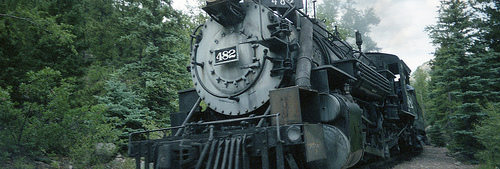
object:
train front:
[127, 0, 350, 168]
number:
[227, 49, 235, 58]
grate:
[193, 133, 250, 168]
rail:
[128, 114, 280, 135]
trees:
[472, 101, 499, 168]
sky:
[110, 0, 498, 82]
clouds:
[113, 0, 498, 82]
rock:
[93, 142, 118, 155]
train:
[126, 0, 426, 168]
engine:
[310, 92, 359, 121]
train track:
[350, 147, 424, 169]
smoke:
[303, 0, 439, 62]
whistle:
[354, 30, 362, 51]